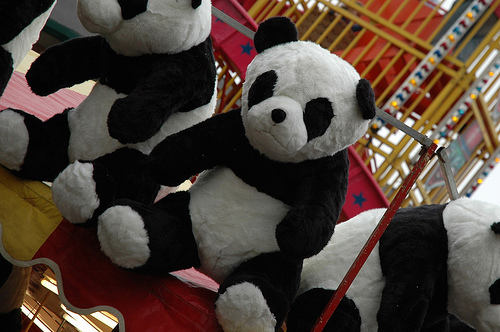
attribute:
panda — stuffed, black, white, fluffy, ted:
[2, 2, 219, 228]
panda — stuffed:
[288, 193, 500, 332]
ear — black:
[250, 14, 301, 56]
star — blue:
[348, 186, 372, 211]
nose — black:
[269, 107, 289, 127]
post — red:
[301, 123, 439, 331]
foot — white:
[93, 200, 160, 278]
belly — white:
[187, 159, 288, 286]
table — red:
[2, 68, 287, 330]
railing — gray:
[211, 2, 470, 205]